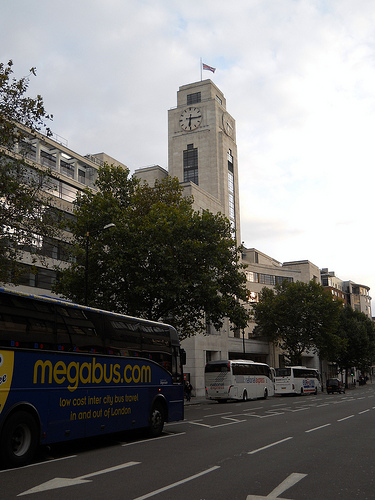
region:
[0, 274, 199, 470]
this bus is blue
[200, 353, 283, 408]
this bus is white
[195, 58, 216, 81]
this is a flag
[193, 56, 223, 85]
the flag is on the tower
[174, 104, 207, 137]
this is a clock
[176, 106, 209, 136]
the clock is on the tower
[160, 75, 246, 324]
this is a tower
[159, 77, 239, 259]
the tower is tall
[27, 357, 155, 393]
the bus says megabus.com on the side of it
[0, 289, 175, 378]
the bus has many windows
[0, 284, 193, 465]
blue and yellow bus on the road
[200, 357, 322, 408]
two white buses parked on the road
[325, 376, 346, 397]
black car stopped in front of the buses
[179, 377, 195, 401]
man waiting for the bus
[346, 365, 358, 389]
stop light at the interection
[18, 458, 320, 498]
white arrows on the road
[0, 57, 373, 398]
green trees along the road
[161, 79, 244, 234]
a tower with clocks on it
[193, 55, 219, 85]
flag on the top of the pole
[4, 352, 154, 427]
advertisement on the side of a bus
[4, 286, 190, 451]
the big blue bus on the street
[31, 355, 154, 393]
the website "megabus.com" on the side of the bus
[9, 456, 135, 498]
the white arrow on the street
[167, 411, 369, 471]
the white dashed lines on the road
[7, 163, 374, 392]
the tall green trees lining the sidewalk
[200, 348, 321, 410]
the two white buses in front of the building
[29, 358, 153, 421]
the yellow letters on the side of the blue bus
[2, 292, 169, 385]
the dark windows on the side of the blue bus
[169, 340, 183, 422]
the door to the bus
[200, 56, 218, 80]
the flag on the top of the building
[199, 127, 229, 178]
edge of a tower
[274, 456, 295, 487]
part of a white line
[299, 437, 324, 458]
part mof a road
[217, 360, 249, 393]
edge of a bus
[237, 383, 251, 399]
part of a wheel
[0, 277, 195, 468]
Blue and yellow Megabus.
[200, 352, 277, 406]
White bus.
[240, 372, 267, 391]
Red and blue lettering on white bus.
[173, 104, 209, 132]
Face of the clock.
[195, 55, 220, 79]
Flag on top of the tower.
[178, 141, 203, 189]
Windows in the side of tower.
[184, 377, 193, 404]
Person walking on sidewalk.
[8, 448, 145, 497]
Arrow painted on the street.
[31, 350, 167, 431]
Yellow lettering on Megabus.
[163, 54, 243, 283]
Rectangular tower.